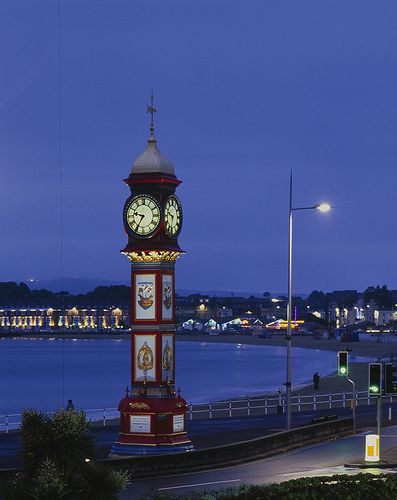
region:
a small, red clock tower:
[108, 88, 194, 453]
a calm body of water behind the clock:
[1, 336, 395, 430]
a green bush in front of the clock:
[4, 408, 132, 498]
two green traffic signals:
[336, 351, 381, 399]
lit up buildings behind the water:
[0, 305, 396, 330]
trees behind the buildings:
[0, 282, 242, 300]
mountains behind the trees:
[19, 276, 312, 303]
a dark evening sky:
[1, 0, 395, 294]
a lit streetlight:
[282, 167, 337, 433]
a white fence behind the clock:
[0, 389, 395, 434]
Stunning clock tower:
[122, 84, 182, 447]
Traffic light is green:
[365, 357, 381, 454]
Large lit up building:
[1, 302, 122, 327]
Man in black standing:
[309, 366, 317, 387]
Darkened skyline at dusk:
[1, 234, 119, 280]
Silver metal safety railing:
[187, 394, 284, 410]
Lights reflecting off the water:
[0, 329, 126, 345]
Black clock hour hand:
[129, 206, 140, 214]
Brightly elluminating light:
[315, 198, 326, 209]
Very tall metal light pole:
[281, 166, 293, 428]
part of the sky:
[236, 10, 293, 98]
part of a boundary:
[165, 448, 196, 469]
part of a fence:
[235, 379, 275, 410]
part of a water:
[185, 345, 222, 391]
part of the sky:
[229, 14, 273, 69]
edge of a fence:
[218, 438, 244, 456]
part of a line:
[207, 469, 229, 487]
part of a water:
[196, 362, 231, 398]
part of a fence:
[203, 394, 238, 425]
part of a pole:
[223, 393, 232, 411]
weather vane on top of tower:
[144, 88, 158, 137]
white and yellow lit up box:
[363, 431, 381, 462]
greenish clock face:
[123, 194, 160, 235]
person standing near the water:
[312, 369, 323, 391]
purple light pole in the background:
[293, 305, 296, 318]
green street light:
[336, 349, 347, 375]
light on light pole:
[286, 165, 330, 424]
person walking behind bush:
[64, 396, 74, 409]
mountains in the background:
[11, 272, 130, 296]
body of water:
[3, 333, 393, 428]